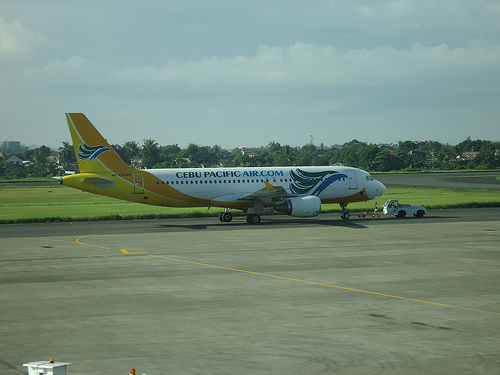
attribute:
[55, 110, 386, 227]
plane — orange, white, yellow, large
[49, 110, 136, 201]
tail — orange, yellow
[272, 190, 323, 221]
engine — white, large, rear side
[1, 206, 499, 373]
pavement — gray, at an airport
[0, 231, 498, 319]
lines — yellow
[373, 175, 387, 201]
nose — white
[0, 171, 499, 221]
grass — green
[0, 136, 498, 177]
trees — green, a lot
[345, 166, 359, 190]
door — white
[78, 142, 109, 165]
logo — blue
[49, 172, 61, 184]
propeller — silvery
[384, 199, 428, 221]
truck — white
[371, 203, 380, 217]
person — walking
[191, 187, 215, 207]
door — for cargo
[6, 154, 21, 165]
house — white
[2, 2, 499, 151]
sky — cloudy, blue